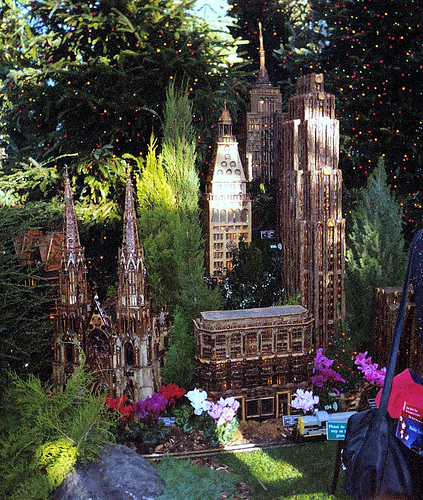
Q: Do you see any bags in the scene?
A: Yes, there is a bag.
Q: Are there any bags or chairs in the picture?
A: Yes, there is a bag.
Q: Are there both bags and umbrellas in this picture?
A: No, there is a bag but no umbrellas.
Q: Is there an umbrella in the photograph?
A: No, there are no umbrellas.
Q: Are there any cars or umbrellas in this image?
A: No, there are no umbrellas or cars.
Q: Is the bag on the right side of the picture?
A: Yes, the bag is on the right of the image.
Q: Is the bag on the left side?
A: No, the bag is on the right of the image.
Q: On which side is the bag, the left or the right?
A: The bag is on the right of the image.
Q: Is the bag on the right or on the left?
A: The bag is on the right of the image.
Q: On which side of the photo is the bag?
A: The bag is on the right of the image.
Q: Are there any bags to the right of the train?
A: Yes, there is a bag to the right of the train.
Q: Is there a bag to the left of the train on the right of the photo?
A: No, the bag is to the right of the train.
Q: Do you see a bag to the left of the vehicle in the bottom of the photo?
A: No, the bag is to the right of the train.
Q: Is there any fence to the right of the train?
A: No, there is a bag to the right of the train.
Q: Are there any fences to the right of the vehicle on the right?
A: No, there is a bag to the right of the train.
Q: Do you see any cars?
A: No, there are no cars.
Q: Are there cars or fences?
A: No, there are no cars or fences.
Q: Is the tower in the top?
A: Yes, the tower is in the top of the image.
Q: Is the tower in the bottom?
A: No, the tower is in the top of the image.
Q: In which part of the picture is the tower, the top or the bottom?
A: The tower is in the top of the image.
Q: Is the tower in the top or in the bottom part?
A: The tower is in the top of the image.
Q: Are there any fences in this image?
A: No, there are no fences.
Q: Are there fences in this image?
A: No, there are no fences.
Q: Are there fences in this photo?
A: No, there are no fences.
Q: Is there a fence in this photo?
A: No, there are no fences.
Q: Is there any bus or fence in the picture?
A: No, there are no fences or buses.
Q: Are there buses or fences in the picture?
A: No, there are no fences or buses.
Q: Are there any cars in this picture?
A: No, there are no cars.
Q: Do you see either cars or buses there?
A: No, there are no cars or buses.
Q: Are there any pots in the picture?
A: No, there are no pots.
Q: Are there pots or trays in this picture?
A: No, there are no pots or trays.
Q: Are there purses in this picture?
A: Yes, there is a purse.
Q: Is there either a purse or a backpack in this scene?
A: Yes, there is a purse.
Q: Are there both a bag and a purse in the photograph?
A: Yes, there are both a purse and a bag.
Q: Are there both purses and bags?
A: Yes, there are both a purse and a bag.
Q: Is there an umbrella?
A: No, there are no umbrellas.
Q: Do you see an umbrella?
A: No, there are no umbrellas.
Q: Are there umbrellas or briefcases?
A: No, there are no umbrellas or briefcases.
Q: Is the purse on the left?
A: No, the purse is on the right of the image.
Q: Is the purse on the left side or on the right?
A: The purse is on the right of the image.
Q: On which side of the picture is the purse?
A: The purse is on the right of the image.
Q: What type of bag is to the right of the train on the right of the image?
A: The bag is a purse.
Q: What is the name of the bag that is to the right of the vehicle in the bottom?
A: The bag is a purse.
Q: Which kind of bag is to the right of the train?
A: The bag is a purse.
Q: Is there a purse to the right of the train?
A: Yes, there is a purse to the right of the train.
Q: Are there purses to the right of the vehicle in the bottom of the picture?
A: Yes, there is a purse to the right of the train.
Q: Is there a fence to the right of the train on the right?
A: No, there is a purse to the right of the train.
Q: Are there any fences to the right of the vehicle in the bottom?
A: No, there is a purse to the right of the train.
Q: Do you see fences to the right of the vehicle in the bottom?
A: No, there is a purse to the right of the train.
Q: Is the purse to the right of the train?
A: Yes, the purse is to the right of the train.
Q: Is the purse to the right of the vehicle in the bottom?
A: Yes, the purse is to the right of the train.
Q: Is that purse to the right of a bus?
A: No, the purse is to the right of the train.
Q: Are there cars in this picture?
A: No, there are no cars.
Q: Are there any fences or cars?
A: No, there are no cars or fences.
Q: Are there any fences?
A: No, there are no fences.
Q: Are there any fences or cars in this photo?
A: No, there are no fences or cars.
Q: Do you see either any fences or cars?
A: No, there are no fences or cars.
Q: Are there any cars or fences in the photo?
A: No, there are no fences or cars.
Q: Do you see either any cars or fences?
A: No, there are no fences or cars.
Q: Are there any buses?
A: No, there are no buses.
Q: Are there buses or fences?
A: No, there are no buses or fences.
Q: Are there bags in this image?
A: Yes, there is a bag.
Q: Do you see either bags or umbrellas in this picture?
A: Yes, there is a bag.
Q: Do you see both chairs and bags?
A: No, there is a bag but no chairs.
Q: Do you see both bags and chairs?
A: No, there is a bag but no chairs.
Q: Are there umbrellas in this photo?
A: No, there are no umbrellas.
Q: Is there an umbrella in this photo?
A: No, there are no umbrellas.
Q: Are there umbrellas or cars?
A: No, there are no umbrellas or cars.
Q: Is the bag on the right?
A: Yes, the bag is on the right of the image.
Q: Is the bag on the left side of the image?
A: No, the bag is on the right of the image.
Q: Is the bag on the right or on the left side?
A: The bag is on the right of the image.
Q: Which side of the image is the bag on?
A: The bag is on the right of the image.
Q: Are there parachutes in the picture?
A: No, there are no parachutes.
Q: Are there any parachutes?
A: No, there are no parachutes.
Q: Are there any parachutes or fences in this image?
A: No, there are no parachutes or fences.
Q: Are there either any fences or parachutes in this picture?
A: No, there are no parachutes or fences.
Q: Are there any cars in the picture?
A: No, there are no cars.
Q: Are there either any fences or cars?
A: No, there are no cars or fences.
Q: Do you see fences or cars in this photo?
A: No, there are no cars or fences.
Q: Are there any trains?
A: Yes, there is a train.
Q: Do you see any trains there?
A: Yes, there is a train.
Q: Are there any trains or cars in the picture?
A: Yes, there is a train.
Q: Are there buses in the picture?
A: No, there are no buses.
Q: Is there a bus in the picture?
A: No, there are no buses.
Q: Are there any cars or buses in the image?
A: No, there are no buses or cars.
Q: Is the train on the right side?
A: Yes, the train is on the right of the image.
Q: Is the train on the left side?
A: No, the train is on the right of the image.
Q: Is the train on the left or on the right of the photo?
A: The train is on the right of the image.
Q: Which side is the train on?
A: The train is on the right of the image.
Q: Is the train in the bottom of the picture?
A: Yes, the train is in the bottom of the image.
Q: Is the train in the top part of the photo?
A: No, the train is in the bottom of the image.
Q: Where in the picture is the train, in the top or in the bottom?
A: The train is in the bottom of the image.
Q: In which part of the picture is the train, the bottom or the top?
A: The train is in the bottom of the image.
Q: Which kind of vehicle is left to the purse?
A: The vehicle is a train.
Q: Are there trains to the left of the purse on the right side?
A: Yes, there is a train to the left of the purse.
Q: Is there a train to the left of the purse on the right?
A: Yes, there is a train to the left of the purse.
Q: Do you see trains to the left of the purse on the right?
A: Yes, there is a train to the left of the purse.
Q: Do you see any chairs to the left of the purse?
A: No, there is a train to the left of the purse.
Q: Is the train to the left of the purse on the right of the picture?
A: Yes, the train is to the left of the purse.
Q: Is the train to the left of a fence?
A: No, the train is to the left of the purse.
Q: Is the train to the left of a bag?
A: Yes, the train is to the left of a bag.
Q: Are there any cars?
A: No, there are no cars.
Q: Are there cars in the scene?
A: No, there are no cars.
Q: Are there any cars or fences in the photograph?
A: No, there are no cars or fences.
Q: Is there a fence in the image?
A: No, there are no fences.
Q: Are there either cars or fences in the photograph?
A: No, there are no fences or cars.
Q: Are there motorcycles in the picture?
A: No, there are no motorcycles.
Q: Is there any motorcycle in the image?
A: No, there are no motorcycles.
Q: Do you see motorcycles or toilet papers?
A: No, there are no motorcycles or toilet papers.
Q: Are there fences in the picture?
A: No, there are no fences.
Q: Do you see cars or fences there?
A: No, there are no fences or cars.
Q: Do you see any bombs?
A: No, there are no bombs.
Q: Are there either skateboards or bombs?
A: No, there are no bombs or skateboards.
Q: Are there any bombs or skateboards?
A: No, there are no bombs or skateboards.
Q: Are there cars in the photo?
A: No, there are no cars.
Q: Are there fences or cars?
A: No, there are no cars or fences.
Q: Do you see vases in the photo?
A: No, there are no vases.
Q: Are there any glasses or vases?
A: No, there are no vases or glasses.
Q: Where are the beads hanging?
A: The beads are hanging in the tree.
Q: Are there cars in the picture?
A: No, there are no cars.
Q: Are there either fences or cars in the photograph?
A: No, there are no cars or fences.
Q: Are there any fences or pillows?
A: No, there are no fences or pillows.